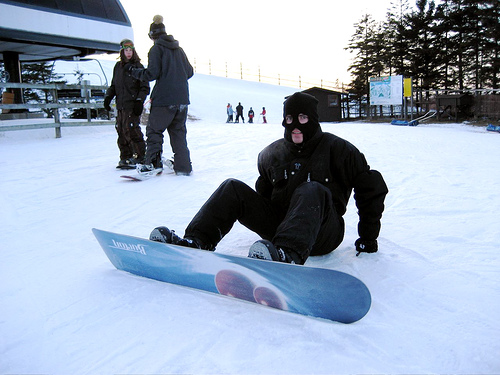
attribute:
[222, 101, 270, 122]
people — group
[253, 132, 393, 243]
jacket — black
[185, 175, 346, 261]
pants — black, grey